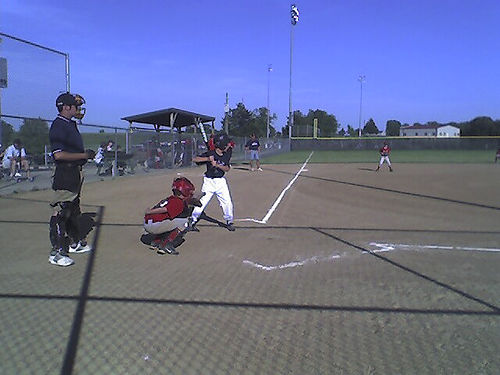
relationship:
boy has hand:
[144, 177, 195, 254] [145, 203, 166, 217]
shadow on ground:
[1, 220, 499, 375] [6, 129, 498, 369]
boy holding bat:
[186, 136, 244, 225] [197, 114, 217, 170]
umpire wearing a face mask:
[49, 91, 93, 267] [57, 89, 91, 127]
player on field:
[375, 141, 392, 171] [2, 147, 496, 365]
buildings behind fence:
[393, 113, 463, 149] [290, 129, 500, 150]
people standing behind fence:
[1, 134, 146, 183] [1, 33, 290, 195]